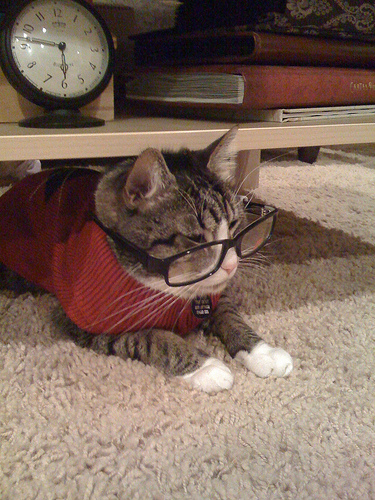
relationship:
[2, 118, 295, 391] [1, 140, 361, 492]
cat in carpet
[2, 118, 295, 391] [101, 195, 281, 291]
cat wearing eye glass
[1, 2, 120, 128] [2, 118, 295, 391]
clock above cat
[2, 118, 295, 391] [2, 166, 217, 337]
cat wearing dress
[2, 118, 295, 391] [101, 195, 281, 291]
cat has eye glass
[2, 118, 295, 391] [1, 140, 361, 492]
cat laying on carpet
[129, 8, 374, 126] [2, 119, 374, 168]
books on table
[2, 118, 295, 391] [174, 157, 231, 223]
cat has stripes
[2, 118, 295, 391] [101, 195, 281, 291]
cat wears eye glass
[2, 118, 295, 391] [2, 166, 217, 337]
cat wears dress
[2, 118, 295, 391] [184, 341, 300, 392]
cat has claws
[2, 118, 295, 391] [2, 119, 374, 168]
cat under table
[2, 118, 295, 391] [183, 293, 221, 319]
cat has tag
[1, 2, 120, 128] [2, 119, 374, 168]
clock on table